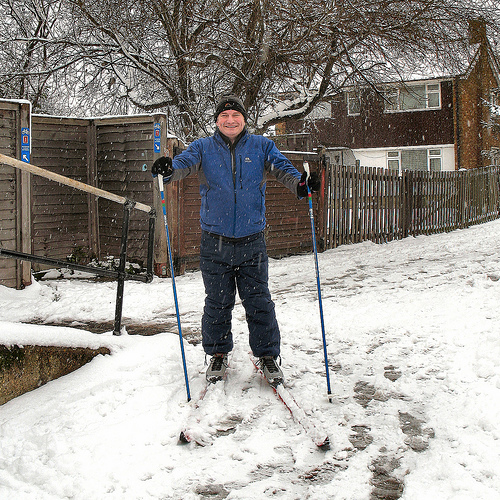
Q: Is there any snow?
A: Yes, there is snow.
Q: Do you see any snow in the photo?
A: Yes, there is snow.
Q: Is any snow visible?
A: Yes, there is snow.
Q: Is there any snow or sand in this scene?
A: Yes, there is snow.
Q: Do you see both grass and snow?
A: No, there is snow but no grass.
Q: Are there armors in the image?
A: No, there are no armors.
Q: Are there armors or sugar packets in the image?
A: No, there are no armors or sugar packets.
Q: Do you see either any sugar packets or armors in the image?
A: No, there are no armors or sugar packets.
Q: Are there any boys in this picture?
A: No, there are no boys.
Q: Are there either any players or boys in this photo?
A: No, there are no boys or players.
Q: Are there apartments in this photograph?
A: No, there are no apartments.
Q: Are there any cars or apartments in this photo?
A: No, there are no apartments or cars.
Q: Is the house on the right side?
A: Yes, the house is on the right of the image.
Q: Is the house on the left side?
A: No, the house is on the right of the image.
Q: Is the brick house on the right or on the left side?
A: The house is on the right of the image.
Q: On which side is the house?
A: The house is on the right of the image.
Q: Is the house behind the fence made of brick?
A: Yes, the house is made of brick.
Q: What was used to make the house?
A: The house is made of brick.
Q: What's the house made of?
A: The house is made of brick.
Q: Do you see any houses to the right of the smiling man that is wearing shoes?
A: Yes, there is a house to the right of the man.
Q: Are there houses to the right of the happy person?
A: Yes, there is a house to the right of the man.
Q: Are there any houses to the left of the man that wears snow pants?
A: No, the house is to the right of the man.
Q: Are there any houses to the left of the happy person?
A: No, the house is to the right of the man.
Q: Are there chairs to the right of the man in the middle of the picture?
A: No, there is a house to the right of the man.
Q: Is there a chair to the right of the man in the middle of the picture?
A: No, there is a house to the right of the man.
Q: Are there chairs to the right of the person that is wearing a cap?
A: No, there is a house to the right of the man.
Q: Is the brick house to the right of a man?
A: Yes, the house is to the right of a man.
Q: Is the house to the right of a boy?
A: No, the house is to the right of a man.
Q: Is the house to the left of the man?
A: No, the house is to the right of the man.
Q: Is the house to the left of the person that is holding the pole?
A: No, the house is to the right of the man.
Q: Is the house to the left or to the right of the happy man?
A: The house is to the right of the man.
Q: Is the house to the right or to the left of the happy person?
A: The house is to the right of the man.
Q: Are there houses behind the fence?
A: Yes, there is a house behind the fence.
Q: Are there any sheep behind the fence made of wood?
A: No, there is a house behind the fence.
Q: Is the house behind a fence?
A: Yes, the house is behind a fence.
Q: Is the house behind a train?
A: No, the house is behind a fence.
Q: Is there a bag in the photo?
A: No, there are no bags.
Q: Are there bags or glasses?
A: No, there are no bags or glasses.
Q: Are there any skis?
A: Yes, there are skis.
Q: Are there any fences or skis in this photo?
A: Yes, there are skis.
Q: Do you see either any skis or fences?
A: Yes, there are skis.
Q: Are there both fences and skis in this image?
A: Yes, there are both skis and a fence.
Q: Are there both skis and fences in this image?
A: Yes, there are both skis and a fence.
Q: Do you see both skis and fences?
A: Yes, there are both skis and a fence.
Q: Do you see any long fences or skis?
A: Yes, there are long skis.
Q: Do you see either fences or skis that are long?
A: Yes, the skis are long.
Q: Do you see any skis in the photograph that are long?
A: Yes, there are long skis.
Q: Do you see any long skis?
A: Yes, there are long skis.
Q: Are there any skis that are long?
A: Yes, there are skis that are long.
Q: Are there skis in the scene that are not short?
A: Yes, there are long skis.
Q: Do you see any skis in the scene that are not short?
A: Yes, there are long skis.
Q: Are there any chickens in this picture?
A: No, there are no chickens.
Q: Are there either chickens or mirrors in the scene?
A: No, there are no chickens or mirrors.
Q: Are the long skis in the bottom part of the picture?
A: Yes, the skis are in the bottom of the image.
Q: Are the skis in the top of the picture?
A: No, the skis are in the bottom of the image.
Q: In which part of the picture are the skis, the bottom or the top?
A: The skis are in the bottom of the image.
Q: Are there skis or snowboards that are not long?
A: No, there are skis but they are long.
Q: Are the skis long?
A: Yes, the skis are long.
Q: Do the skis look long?
A: Yes, the skis are long.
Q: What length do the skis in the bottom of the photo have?
A: The skis have long length.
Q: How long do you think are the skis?
A: The skis are long.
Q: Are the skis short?
A: No, the skis are long.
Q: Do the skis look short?
A: No, the skis are long.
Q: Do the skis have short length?
A: No, the skis are long.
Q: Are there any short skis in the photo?
A: No, there are skis but they are long.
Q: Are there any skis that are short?
A: No, there are skis but they are long.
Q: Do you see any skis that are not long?
A: No, there are skis but they are long.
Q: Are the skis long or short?
A: The skis are long.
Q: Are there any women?
A: No, there are no women.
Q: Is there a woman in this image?
A: No, there are no women.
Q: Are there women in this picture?
A: No, there are no women.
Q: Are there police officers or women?
A: No, there are no women or police officers.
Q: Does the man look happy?
A: Yes, the man is happy.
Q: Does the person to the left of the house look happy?
A: Yes, the man is happy.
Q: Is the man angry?
A: No, the man is happy.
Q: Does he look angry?
A: No, the man is happy.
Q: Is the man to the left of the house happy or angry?
A: The man is happy.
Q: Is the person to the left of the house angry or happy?
A: The man is happy.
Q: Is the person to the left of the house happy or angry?
A: The man is happy.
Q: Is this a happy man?
A: Yes, this is a happy man.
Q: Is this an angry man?
A: No, this is a happy man.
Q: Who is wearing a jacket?
A: The man is wearing a jacket.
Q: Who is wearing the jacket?
A: The man is wearing a jacket.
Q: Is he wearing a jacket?
A: Yes, the man is wearing a jacket.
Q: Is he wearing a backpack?
A: No, the man is wearing a jacket.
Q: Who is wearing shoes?
A: The man is wearing shoes.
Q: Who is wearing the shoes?
A: The man is wearing shoes.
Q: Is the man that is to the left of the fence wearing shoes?
A: Yes, the man is wearing shoes.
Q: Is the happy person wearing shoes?
A: Yes, the man is wearing shoes.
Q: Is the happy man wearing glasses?
A: No, the man is wearing shoes.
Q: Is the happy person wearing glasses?
A: No, the man is wearing shoes.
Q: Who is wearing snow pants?
A: The man is wearing snow pants.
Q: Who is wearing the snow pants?
A: The man is wearing snow pants.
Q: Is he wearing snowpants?
A: Yes, the man is wearing snowpants.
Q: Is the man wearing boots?
A: No, the man is wearing snowpants.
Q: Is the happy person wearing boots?
A: No, the man is wearing snowpants.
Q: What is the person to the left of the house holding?
A: The man is holding the pole.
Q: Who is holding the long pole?
A: The man is holding the pole.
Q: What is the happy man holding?
A: The man is holding the pole.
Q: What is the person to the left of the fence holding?
A: The man is holding the pole.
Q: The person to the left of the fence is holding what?
A: The man is holding the pole.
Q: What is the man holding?
A: The man is holding the pole.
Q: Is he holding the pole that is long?
A: Yes, the man is holding the pole.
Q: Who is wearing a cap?
A: The man is wearing a cap.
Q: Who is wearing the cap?
A: The man is wearing a cap.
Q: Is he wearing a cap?
A: Yes, the man is wearing a cap.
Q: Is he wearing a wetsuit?
A: No, the man is wearing a cap.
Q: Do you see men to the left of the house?
A: Yes, there is a man to the left of the house.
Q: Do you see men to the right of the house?
A: No, the man is to the left of the house.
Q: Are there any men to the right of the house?
A: No, the man is to the left of the house.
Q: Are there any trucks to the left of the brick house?
A: No, there is a man to the left of the house.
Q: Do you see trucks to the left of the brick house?
A: No, there is a man to the left of the house.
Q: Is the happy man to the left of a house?
A: Yes, the man is to the left of a house.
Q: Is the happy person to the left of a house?
A: Yes, the man is to the left of a house.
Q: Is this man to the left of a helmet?
A: No, the man is to the left of a house.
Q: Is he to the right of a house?
A: No, the man is to the left of a house.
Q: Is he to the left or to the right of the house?
A: The man is to the left of the house.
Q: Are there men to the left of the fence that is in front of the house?
A: Yes, there is a man to the left of the fence.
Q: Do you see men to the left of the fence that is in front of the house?
A: Yes, there is a man to the left of the fence.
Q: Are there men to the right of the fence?
A: No, the man is to the left of the fence.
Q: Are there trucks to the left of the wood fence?
A: No, there is a man to the left of the fence.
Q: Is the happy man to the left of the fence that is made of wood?
A: Yes, the man is to the left of the fence.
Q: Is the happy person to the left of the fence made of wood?
A: Yes, the man is to the left of the fence.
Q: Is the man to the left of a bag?
A: No, the man is to the left of the fence.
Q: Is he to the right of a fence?
A: No, the man is to the left of a fence.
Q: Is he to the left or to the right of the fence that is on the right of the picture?
A: The man is to the left of the fence.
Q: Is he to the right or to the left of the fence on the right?
A: The man is to the left of the fence.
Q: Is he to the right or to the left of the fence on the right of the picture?
A: The man is to the left of the fence.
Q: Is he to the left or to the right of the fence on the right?
A: The man is to the left of the fence.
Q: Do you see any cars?
A: No, there are no cars.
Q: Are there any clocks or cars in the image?
A: No, there are no cars or clocks.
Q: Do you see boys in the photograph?
A: No, there are no boys.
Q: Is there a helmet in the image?
A: No, there are no helmets.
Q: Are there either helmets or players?
A: No, there are no helmets or players.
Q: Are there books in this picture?
A: No, there are no books.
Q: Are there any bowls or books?
A: No, there are no books or bowls.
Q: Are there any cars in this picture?
A: No, there are no cars.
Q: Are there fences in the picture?
A: Yes, there is a fence.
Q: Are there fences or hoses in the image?
A: Yes, there is a fence.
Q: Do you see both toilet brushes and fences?
A: No, there is a fence but no toilet brushes.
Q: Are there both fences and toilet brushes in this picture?
A: No, there is a fence but no toilet brushes.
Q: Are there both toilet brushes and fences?
A: No, there is a fence but no toilet brushes.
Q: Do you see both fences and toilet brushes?
A: No, there is a fence but no toilet brushes.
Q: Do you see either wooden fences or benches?
A: Yes, there is a wood fence.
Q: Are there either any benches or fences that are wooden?
A: Yes, the fence is wooden.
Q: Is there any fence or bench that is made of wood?
A: Yes, the fence is made of wood.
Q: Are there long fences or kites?
A: Yes, there is a long fence.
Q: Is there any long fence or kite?
A: Yes, there is a long fence.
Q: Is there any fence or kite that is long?
A: Yes, the fence is long.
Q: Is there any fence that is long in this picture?
A: Yes, there is a long fence.